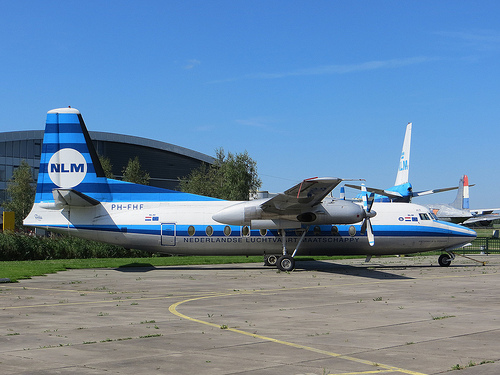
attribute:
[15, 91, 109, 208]
tail — vintage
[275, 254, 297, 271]
tire — round, rubber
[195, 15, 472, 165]
sky — blue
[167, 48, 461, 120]
clouds — white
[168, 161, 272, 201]
hedge — green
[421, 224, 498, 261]
fence — iron and black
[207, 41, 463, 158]
clouds — white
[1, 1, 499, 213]
sky — blue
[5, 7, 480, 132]
sky — blue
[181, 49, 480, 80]
clouds — white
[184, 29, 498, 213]
clouds — white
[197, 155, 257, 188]
hedge — green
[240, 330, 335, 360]
lines — yellow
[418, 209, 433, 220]
windows — small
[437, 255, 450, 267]
wheel — black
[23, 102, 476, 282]
airplane — blue and white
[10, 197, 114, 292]
post — yellow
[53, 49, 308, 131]
clouds — white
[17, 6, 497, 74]
sky — blue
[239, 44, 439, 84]
clouds — white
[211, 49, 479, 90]
clouds — white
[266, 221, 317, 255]
gear — landing